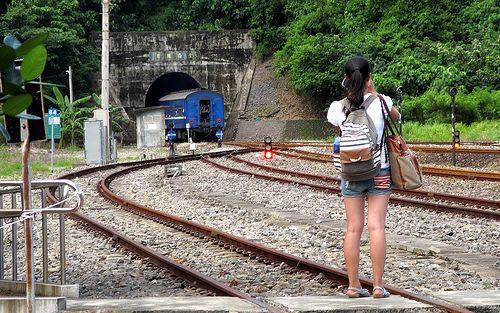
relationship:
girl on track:
[327, 57, 400, 295] [46, 140, 474, 312]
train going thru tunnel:
[157, 88, 226, 138] [146, 73, 201, 108]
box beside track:
[85, 119, 116, 165] [46, 140, 474, 312]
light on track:
[265, 137, 273, 158] [46, 140, 474, 312]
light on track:
[454, 130, 460, 149] [46, 140, 474, 312]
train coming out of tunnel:
[157, 88, 226, 138] [146, 73, 201, 108]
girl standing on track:
[327, 57, 400, 295] [46, 140, 474, 312]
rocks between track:
[1, 137, 347, 298] [46, 140, 474, 312]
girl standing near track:
[327, 57, 400, 295] [46, 140, 474, 312]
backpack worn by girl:
[334, 92, 380, 183] [327, 57, 400, 295]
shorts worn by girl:
[341, 166, 392, 196] [327, 57, 400, 295]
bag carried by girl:
[378, 93, 423, 190] [327, 57, 400, 295]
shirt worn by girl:
[327, 93, 393, 170] [327, 57, 400, 295]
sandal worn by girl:
[348, 286, 370, 297] [327, 57, 400, 295]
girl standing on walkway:
[327, 57, 400, 295] [66, 288, 499, 310]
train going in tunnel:
[157, 88, 226, 138] [146, 73, 201, 108]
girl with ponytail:
[327, 57, 400, 295] [343, 55, 369, 108]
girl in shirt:
[327, 57, 400, 295] [327, 93, 393, 170]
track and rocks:
[46, 140, 474, 312] [1, 137, 347, 298]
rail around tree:
[1, 179, 83, 282] [19, 67, 36, 310]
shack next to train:
[133, 105, 167, 150] [157, 88, 226, 138]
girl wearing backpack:
[327, 57, 400, 295] [334, 92, 380, 183]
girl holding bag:
[327, 57, 400, 295] [378, 93, 423, 190]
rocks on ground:
[1, 137, 347, 298] [0, 120, 499, 312]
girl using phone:
[327, 57, 400, 295] [342, 76, 349, 88]